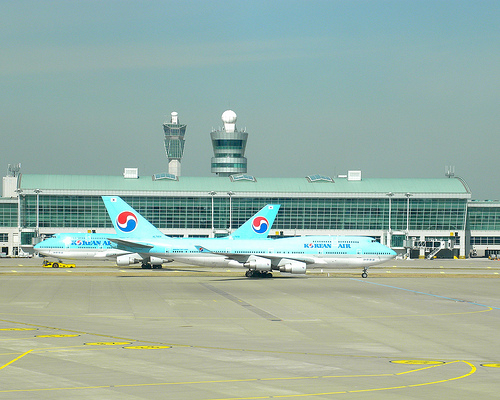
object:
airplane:
[101, 195, 398, 277]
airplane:
[33, 204, 282, 269]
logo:
[116, 211, 139, 234]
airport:
[0, 109, 500, 400]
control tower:
[210, 109, 248, 177]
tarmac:
[1, 258, 499, 399]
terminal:
[1, 109, 498, 259]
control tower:
[162, 111, 187, 177]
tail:
[101, 196, 175, 262]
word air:
[338, 244, 351, 249]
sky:
[1, 0, 499, 200]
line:
[0, 305, 492, 319]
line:
[0, 360, 477, 400]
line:
[0, 348, 35, 371]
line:
[34, 345, 122, 351]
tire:
[362, 273, 368, 278]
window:
[480, 236, 488, 246]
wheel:
[158, 265, 162, 269]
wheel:
[152, 265, 156, 268]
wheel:
[147, 264, 152, 269]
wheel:
[141, 264, 146, 269]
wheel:
[267, 273, 272, 278]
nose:
[378, 246, 398, 260]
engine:
[243, 259, 271, 271]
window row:
[173, 250, 390, 255]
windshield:
[371, 240, 377, 243]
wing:
[194, 245, 327, 266]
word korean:
[303, 243, 331, 248]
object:
[221, 109, 237, 131]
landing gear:
[362, 267, 368, 273]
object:
[42, 262, 76, 268]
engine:
[279, 262, 306, 274]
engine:
[116, 256, 139, 266]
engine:
[150, 256, 171, 265]